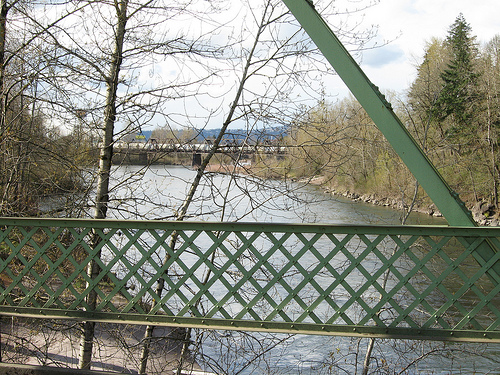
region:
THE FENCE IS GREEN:
[295, 254, 305, 274]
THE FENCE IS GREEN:
[296, 282, 304, 299]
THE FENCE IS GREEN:
[293, 298, 313, 310]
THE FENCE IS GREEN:
[289, 280, 304, 298]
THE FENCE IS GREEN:
[307, 284, 328, 314]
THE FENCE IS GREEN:
[292, 275, 309, 299]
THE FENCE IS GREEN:
[292, 287, 307, 307]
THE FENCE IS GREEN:
[296, 272, 322, 307]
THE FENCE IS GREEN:
[284, 297, 299, 312]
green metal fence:
[64, 212, 476, 311]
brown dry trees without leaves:
[69, 5, 284, 145]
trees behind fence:
[47, 18, 293, 190]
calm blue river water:
[242, 187, 366, 232]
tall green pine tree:
[418, 28, 494, 108]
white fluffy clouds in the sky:
[361, 6, 446, 68]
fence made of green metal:
[10, 216, 445, 321]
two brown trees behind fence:
[3, 13, 292, 271]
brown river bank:
[154, 322, 251, 369]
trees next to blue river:
[320, 119, 403, 204]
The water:
[245, 167, 310, 241]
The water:
[272, 338, 309, 370]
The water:
[300, 352, 332, 369]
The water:
[228, 325, 286, 372]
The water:
[235, 361, 255, 372]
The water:
[247, 340, 277, 368]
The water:
[230, 274, 347, 365]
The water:
[234, 311, 284, 346]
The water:
[248, 352, 336, 371]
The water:
[246, 356, 306, 373]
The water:
[289, 364, 310, 372]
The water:
[266, 301, 371, 373]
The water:
[256, 331, 336, 371]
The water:
[235, 313, 319, 368]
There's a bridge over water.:
[49, 130, 296, 183]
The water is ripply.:
[53, 152, 498, 371]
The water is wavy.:
[50, 154, 498, 373]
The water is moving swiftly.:
[51, 145, 495, 372]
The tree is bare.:
[37, 3, 182, 372]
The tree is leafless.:
[39, 4, 144, 372]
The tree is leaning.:
[45, 1, 176, 373]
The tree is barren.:
[31, 0, 161, 374]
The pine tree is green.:
[426, 14, 491, 158]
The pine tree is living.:
[422, 9, 489, 157]